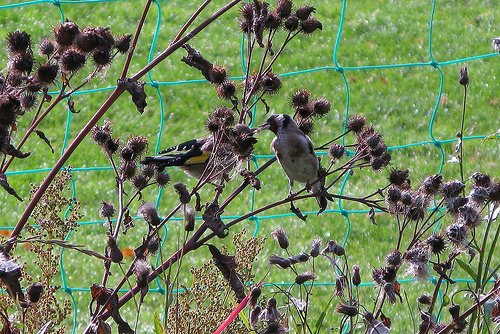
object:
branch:
[186, 153, 279, 250]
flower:
[347, 264, 363, 286]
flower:
[413, 291, 435, 307]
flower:
[445, 305, 462, 320]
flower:
[130, 256, 150, 281]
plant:
[113, 32, 133, 54]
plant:
[180, 207, 197, 234]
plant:
[268, 223, 292, 255]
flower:
[309, 98, 335, 117]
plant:
[247, 284, 262, 309]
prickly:
[466, 180, 490, 209]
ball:
[270, 228, 292, 249]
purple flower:
[0, 26, 33, 56]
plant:
[94, 199, 118, 220]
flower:
[87, 118, 113, 147]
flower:
[385, 164, 410, 187]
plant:
[134, 199, 164, 229]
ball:
[90, 46, 114, 69]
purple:
[24, 279, 44, 304]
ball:
[470, 171, 492, 188]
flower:
[56, 47, 84, 75]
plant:
[13, 91, 38, 114]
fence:
[0, 0, 499, 333]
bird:
[256, 113, 335, 217]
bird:
[137, 123, 262, 196]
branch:
[127, 0, 243, 89]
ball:
[344, 113, 364, 133]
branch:
[290, 153, 396, 217]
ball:
[28, 282, 44, 305]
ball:
[379, 265, 398, 286]